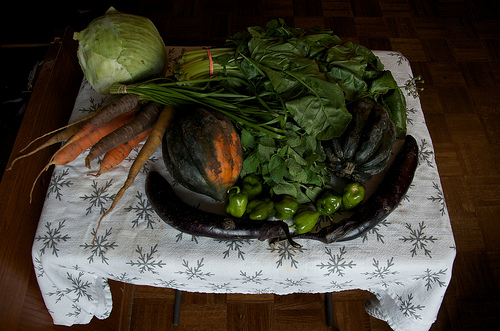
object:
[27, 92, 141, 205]
carrots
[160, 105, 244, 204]
squash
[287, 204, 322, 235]
peppers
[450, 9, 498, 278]
floor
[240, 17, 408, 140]
greens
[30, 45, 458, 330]
tablecloth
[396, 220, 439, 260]
snowflakes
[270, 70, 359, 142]
leaf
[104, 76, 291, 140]
onions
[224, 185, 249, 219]
pepper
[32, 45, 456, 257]
tray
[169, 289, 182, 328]
legs